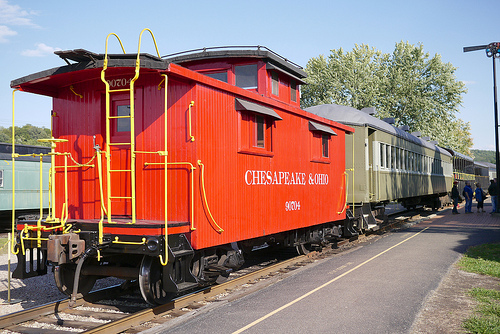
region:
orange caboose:
[44, 45, 349, 256]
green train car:
[348, 115, 445, 220]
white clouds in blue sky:
[86, 4, 122, 37]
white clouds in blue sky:
[18, 22, 38, 48]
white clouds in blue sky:
[222, 19, 256, 34]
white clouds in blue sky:
[138, 14, 182, 54]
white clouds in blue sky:
[419, 14, 455, 36]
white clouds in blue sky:
[328, 18, 370, 45]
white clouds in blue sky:
[255, 18, 316, 38]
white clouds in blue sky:
[464, 59, 481, 122]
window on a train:
[242, 115, 274, 149]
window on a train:
[233, 59, 265, 90]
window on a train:
[115, 101, 130, 131]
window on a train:
[378, 136, 383, 166]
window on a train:
[268, 69, 285, 94]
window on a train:
[287, 79, 299, 101]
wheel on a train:
[138, 244, 182, 306]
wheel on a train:
[51, 256, 96, 298]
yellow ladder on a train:
[97, 65, 144, 228]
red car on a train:
[3, 32, 364, 310]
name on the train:
[234, 161, 344, 198]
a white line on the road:
[248, 225, 443, 317]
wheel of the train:
[123, 244, 188, 311]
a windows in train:
[369, 138, 468, 180]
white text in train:
[236, 160, 344, 201]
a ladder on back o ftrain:
[83, 49, 151, 238]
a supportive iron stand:
[5, 150, 198, 239]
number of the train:
[280, 194, 311, 216]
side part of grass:
[442, 230, 493, 330]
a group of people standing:
[448, 158, 498, 227]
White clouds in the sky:
[1, 2, 64, 64]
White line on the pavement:
[231, 225, 428, 331]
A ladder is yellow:
[101, 25, 159, 225]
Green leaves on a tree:
[297, 38, 476, 161]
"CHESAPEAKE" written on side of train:
[241, 166, 308, 191]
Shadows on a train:
[387, 123, 449, 200]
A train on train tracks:
[0, 24, 497, 331]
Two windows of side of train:
[231, 95, 338, 166]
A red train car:
[6, 25, 358, 307]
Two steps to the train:
[157, 226, 205, 300]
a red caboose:
[6, 24, 353, 310]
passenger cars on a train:
[309, 94, 493, 222]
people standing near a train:
[448, 176, 499, 214]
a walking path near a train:
[253, 210, 443, 332]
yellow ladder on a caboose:
[98, 61, 143, 236]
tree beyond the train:
[294, 34, 486, 151]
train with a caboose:
[4, 16, 496, 321]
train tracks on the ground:
[2, 281, 182, 328]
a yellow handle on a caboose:
[188, 99, 196, 147]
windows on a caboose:
[229, 92, 338, 165]